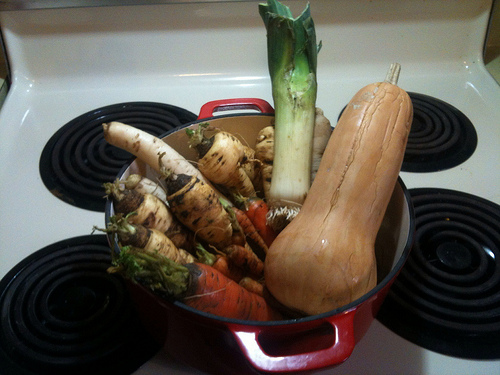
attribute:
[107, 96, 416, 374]
pot — red